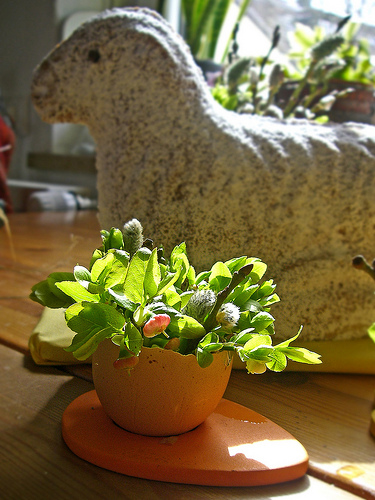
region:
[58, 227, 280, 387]
green plants growing in a planter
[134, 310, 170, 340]
red blossom of the plant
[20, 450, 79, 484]
wood surface of the table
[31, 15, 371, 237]
a large fake sheep on the table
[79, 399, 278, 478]
orange clay base of the planter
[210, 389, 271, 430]
water on the planter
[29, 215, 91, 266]
glossy wood surface of the couter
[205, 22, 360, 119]
plants growing behind the sheep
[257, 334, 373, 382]
yellow cloth on a base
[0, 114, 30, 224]
red towel on a hook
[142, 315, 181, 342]
single pink flower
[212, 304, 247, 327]
green flower buds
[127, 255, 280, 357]
green flowers in pot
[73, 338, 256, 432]
red clay flower pot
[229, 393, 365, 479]
water spots on surface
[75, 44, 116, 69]
black eye on stone toy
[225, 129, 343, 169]
lines on the statue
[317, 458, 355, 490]
break in the brown table top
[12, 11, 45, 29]
gray paint on the wall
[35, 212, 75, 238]
shine on the table top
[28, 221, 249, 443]
flowers in a clay pot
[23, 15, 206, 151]
head of an ornamental sheep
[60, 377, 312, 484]
a flowerpot stand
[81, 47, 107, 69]
eye of the ornamental sheep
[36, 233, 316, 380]
plant in a ceramic pot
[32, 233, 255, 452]
plant in a pot in front of an ornamental sheep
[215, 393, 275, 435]
some water on pot stand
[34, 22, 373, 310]
sheep made out of porcalein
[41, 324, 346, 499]
potplant and a stand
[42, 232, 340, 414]
leafy flowers in a pot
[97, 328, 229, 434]
the red pot on the floor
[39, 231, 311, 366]
the flowers in the pot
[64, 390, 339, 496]
the base of the pot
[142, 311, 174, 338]
the red flower in the pot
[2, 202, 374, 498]
the hardwood floor in the room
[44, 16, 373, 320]
the sheep on the floor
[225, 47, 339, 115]
the plant behind the sheep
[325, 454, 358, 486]
the stain on the floor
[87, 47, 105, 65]
the eye of the sheep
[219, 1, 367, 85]
the window behind the sheep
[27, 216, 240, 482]
Plant growing in an egg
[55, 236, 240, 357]
The plant is leafy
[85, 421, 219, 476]
Egg is sitting on a board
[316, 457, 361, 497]
Crack in the table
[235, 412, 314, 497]
Light reflecting on the table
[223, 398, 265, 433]
water on the board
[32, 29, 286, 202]
Cement lamb on the table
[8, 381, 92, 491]
The table is made of wood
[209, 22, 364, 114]
Plants in the window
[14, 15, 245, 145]
The lamb is made of concrete